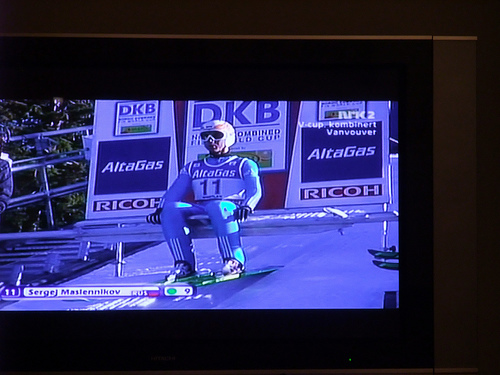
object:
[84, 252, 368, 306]
snow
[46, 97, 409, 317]
screen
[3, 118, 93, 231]
rail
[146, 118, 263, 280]
man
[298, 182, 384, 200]
sign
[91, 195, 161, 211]
sign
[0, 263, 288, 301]
ski jump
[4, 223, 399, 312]
wall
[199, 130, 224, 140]
goggles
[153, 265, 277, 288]
ski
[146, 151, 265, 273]
blue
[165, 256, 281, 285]
green skis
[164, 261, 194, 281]
ski boot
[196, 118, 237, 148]
helmet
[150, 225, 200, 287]
boot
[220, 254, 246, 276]
shoes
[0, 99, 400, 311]
screen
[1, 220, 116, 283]
steps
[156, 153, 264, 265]
outfit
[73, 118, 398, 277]
bench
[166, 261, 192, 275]
feet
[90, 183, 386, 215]
letters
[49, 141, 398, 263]
platform